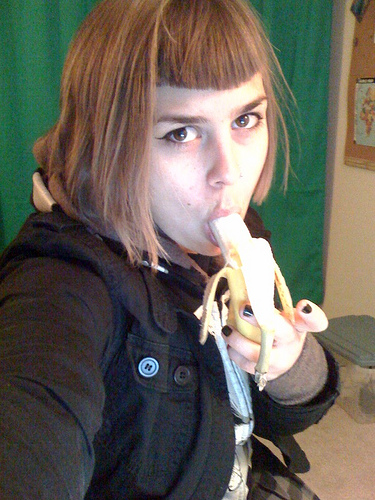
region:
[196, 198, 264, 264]
mouth wrapped around banana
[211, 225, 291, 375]
partially peeled banana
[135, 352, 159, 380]
small black four-holed button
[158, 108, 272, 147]
woman has brown eyes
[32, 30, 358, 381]
woman eating a banana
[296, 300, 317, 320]
shiny black nail polish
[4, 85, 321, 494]
woman is wearing a dark jacket with black buttons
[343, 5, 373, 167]
corkboard with a print of world map pinned to it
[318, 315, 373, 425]
small plastic bin with light blue lid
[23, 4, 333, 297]
woman being suggestive with banana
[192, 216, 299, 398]
a half peeled banana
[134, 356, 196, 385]
a pair of black buttons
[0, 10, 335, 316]
a green curtain in the background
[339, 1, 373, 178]
an old corkboard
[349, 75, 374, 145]
a picture of a map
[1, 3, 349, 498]
a girl eating a banana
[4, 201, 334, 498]
a light black jacket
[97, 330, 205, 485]
a pocket with a flap enclosure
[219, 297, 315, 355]
some finger nails painted black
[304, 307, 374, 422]
plastic container with grey lid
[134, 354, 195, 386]
black buttons on the pocket of a shirt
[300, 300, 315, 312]
black finger nail polish on her pointer finger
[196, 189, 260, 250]
a woman's mouth around a banana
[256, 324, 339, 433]
a brown sleeve under a black jacket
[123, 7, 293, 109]
short cut brown bangs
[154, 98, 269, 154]
a woman's brown eyes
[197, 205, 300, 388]
a peeled yellow banana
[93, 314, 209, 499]
black pocket of a jacket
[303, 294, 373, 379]
gray storage container lid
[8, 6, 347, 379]
a woman with a banana in her mouth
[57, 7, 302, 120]
The girl has bangs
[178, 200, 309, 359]
She is eating a banana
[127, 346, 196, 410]
Buttons on front of coat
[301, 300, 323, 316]
Woman wearing dark nail polish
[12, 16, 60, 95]
Green sheet hanging in background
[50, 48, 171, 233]
Woman has brown hair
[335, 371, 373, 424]
Shadow on the ground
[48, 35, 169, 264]
The girl has short hair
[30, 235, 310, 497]
she is wearing a black jacket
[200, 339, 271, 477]
Shirt underneath jacket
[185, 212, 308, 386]
banana in woman's mouth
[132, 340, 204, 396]
buttons on woman's pocket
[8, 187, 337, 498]
black coat of woman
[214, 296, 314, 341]
black fingernails of woman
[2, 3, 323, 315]
green curtain behind woman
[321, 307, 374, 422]
plastic container gray lid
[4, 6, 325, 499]
woman eating banana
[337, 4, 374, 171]
corkboard on wall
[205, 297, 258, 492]
shirt of woman wearing black coat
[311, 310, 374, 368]
lid of plastic container